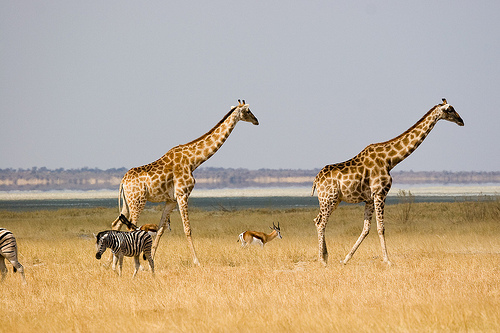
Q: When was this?
A: Daytime.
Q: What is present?
A: Animals.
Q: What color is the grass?
A: Brown.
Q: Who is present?
A: Nobody.